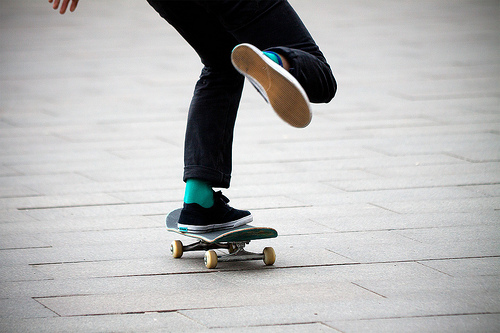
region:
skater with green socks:
[183, 171, 220, 211]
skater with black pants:
[139, 0, 363, 240]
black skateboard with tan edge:
[159, 201, 286, 249]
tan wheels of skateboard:
[163, 239, 288, 274]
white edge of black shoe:
[229, 38, 322, 130]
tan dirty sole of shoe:
[221, 41, 325, 126]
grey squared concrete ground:
[293, 208, 407, 320]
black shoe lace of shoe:
[215, 186, 252, 221]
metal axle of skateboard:
[219, 241, 264, 272]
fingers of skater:
[50, 0, 80, 12]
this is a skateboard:
[162, 212, 277, 265]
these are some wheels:
[165, 245, 281, 267]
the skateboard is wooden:
[203, 225, 271, 237]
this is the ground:
[338, 143, 448, 328]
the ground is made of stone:
[332, 183, 404, 267]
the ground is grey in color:
[309, 175, 414, 298]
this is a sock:
[187, 182, 211, 202]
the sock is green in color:
[185, 182, 207, 202]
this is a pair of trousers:
[167, 5, 284, 37]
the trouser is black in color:
[243, 5, 288, 35]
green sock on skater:
[178, 177, 225, 208]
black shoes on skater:
[175, 188, 259, 233]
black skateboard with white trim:
[153, 193, 273, 248]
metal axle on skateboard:
[216, 248, 268, 268]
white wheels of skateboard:
[165, 235, 283, 270]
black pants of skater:
[146, 1, 323, 276]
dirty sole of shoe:
[232, 55, 302, 127]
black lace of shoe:
[217, 183, 228, 218]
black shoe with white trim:
[174, 188, 261, 232]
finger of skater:
[38, 0, 78, 19]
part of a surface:
[384, 140, 441, 192]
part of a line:
[306, 253, 327, 270]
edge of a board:
[233, 219, 269, 239]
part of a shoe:
[179, 195, 216, 223]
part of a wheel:
[189, 237, 241, 304]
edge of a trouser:
[175, 150, 229, 197]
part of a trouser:
[199, 120, 224, 147]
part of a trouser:
[186, 110, 224, 157]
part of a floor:
[333, 230, 385, 290]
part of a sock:
[194, 187, 208, 207]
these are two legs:
[163, 50, 305, 184]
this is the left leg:
[181, 121, 234, 224]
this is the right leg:
[233, 41, 331, 83]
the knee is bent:
[323, 69, 334, 99]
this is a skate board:
[185, 225, 280, 274]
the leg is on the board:
[193, 195, 244, 232]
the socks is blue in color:
[187, 184, 205, 201]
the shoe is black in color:
[193, 208, 232, 228]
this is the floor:
[357, 148, 482, 285]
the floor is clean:
[337, 152, 482, 289]